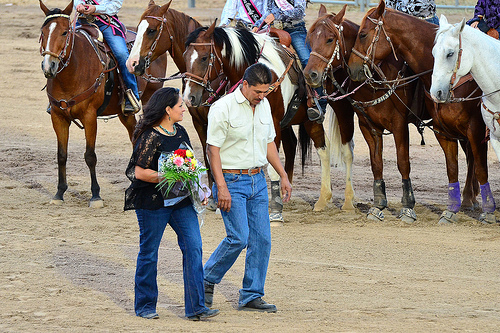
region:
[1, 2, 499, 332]
brown horses behind a man and woman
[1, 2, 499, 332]
two people walking in front of horses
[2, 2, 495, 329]
horses and a couple on a dirt ground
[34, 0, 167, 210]
person sitting on a brown horse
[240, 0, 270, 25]
black white and pink sash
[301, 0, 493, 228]
brown and white horses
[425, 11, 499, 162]
brown harness over the face of a white horse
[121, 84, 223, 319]
woman walking with a bouquet of flowers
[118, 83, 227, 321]
woman in a black top holding a bouquet of flowers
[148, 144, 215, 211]
colorful bouquet of flowers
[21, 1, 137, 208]
brown horse standing on dirt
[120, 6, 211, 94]
brown horse standing on dirt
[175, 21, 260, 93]
brown horse standing on dirt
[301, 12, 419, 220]
brown horse standing on dirt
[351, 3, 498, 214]
brown horse standing on dirt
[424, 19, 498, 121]
white horse on side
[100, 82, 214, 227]
woman carrying flower bouquet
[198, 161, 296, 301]
man wearing blue jeans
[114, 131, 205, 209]
woman wearing a black blouse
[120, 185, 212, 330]
woman wearing blue jeans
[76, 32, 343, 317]
two people walking together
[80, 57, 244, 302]
a woman with a bouquet of flowers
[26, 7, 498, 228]
a line of standing horses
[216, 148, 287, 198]
a brown belt on man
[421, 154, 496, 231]
purple cloth on horse ankle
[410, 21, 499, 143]
a head of a white horse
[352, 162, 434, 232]
black cloth on horse ankles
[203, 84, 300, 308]
a white shirt and jeans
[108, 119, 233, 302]
a black shirt and jeans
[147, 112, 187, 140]
a necklace and earring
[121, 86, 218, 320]
a woman wearing blue jeans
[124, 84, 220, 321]
the woman has black colored hair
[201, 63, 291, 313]
a man wearing a brown belt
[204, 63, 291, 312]
a man with dark hair and wearing blue jeans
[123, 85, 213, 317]
a woman wearing a black shirt and necklace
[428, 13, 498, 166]
a white horse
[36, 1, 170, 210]
a person wearing blue jeans sitting on a horse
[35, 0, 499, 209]
six horses standing in the sand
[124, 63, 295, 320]
two dark haired people walking in the sand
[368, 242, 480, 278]
the sand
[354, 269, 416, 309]
the sand is brown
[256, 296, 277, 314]
man is wearing black shoes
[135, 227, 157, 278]
dark blue jeans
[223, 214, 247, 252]
man is wearing light blue jeans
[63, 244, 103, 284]
a shadow in the sand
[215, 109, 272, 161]
a shirt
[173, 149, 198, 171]
women is carrying flowers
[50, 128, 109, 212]
the horses legs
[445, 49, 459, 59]
the eye on the horse